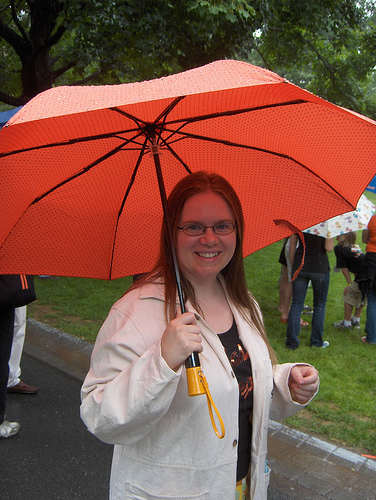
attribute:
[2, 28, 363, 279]
umbrella — red, yellow, white, opened, colorful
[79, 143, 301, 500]
woman — wearing glass, white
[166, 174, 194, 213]
hair — brown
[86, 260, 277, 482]
jacket — white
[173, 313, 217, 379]
handle — black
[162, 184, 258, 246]
glass — black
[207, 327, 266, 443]
top — black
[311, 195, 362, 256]
umbrella — white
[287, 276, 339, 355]
lady — wearing, blue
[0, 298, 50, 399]
pant — white, short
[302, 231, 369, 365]
kid — holding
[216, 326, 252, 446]
shirt — black, orange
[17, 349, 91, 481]
road — paved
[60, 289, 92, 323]
grass — green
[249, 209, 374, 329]
people — three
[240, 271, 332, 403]
jean — blue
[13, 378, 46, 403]
shoe — brown